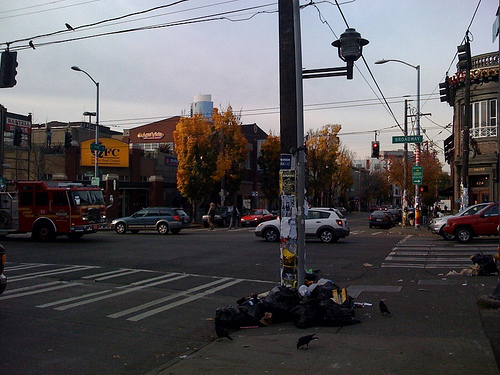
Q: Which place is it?
A: It is a road.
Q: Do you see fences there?
A: No, there are no fences.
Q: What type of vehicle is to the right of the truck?
A: The vehicle is a car.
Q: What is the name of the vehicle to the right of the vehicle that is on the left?
A: The vehicle is a car.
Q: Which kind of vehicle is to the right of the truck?
A: The vehicle is a car.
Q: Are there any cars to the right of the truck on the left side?
A: Yes, there is a car to the right of the truck.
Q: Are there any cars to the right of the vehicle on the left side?
A: Yes, there is a car to the right of the truck.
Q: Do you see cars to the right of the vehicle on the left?
A: Yes, there is a car to the right of the truck.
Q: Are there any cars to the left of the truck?
A: No, the car is to the right of the truck.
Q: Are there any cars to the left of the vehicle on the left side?
A: No, the car is to the right of the truck.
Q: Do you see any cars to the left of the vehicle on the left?
A: No, the car is to the right of the truck.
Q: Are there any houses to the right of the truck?
A: No, there is a car to the right of the truck.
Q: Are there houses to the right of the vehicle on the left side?
A: No, there is a car to the right of the truck.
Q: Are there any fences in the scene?
A: No, there are no fences.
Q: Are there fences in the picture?
A: No, there are no fences.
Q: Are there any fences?
A: No, there are no fences.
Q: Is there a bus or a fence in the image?
A: No, there are no fences or buses.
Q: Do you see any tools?
A: No, there are no tools.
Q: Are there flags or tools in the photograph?
A: No, there are no tools or flags.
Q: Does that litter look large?
A: Yes, the litter is large.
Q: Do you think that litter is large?
A: Yes, the litter is large.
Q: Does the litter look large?
A: Yes, the litter is large.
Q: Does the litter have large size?
A: Yes, the litter is large.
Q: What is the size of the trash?
A: The trash is large.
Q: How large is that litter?
A: The litter is large.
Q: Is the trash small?
A: No, the trash is large.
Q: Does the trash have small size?
A: No, the trash is large.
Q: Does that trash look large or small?
A: The trash is large.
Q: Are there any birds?
A: Yes, there is a bird.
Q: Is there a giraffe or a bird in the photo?
A: Yes, there is a bird.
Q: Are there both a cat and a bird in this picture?
A: No, there is a bird but no cats.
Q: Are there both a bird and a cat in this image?
A: No, there is a bird but no cats.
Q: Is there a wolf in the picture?
A: No, there are no wolves.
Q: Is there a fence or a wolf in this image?
A: No, there are no wolves or fences.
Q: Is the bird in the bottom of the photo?
A: Yes, the bird is in the bottom of the image.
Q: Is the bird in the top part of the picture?
A: No, the bird is in the bottom of the image.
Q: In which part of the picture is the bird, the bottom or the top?
A: The bird is in the bottom of the image.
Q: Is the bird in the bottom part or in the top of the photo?
A: The bird is in the bottom of the image.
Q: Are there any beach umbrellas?
A: No, there are no beach umbrellas.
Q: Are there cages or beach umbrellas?
A: No, there are no beach umbrellas or cages.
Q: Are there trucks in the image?
A: Yes, there is a truck.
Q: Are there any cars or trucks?
A: Yes, there is a truck.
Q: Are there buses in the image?
A: No, there are no buses.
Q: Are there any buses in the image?
A: No, there are no buses.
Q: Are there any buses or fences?
A: No, there are no buses or fences.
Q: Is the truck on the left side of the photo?
A: Yes, the truck is on the left of the image.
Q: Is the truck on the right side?
A: No, the truck is on the left of the image.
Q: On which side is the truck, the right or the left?
A: The truck is on the left of the image.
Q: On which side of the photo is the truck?
A: The truck is on the left of the image.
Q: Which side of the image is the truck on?
A: The truck is on the left of the image.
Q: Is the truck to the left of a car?
A: Yes, the truck is to the left of a car.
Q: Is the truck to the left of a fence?
A: No, the truck is to the left of a car.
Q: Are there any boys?
A: No, there are no boys.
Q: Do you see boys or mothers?
A: No, there are no boys or mothers.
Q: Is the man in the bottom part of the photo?
A: Yes, the man is in the bottom of the image.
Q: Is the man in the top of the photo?
A: No, the man is in the bottom of the image.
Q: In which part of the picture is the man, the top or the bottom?
A: The man is in the bottom of the image.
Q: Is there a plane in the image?
A: No, there are no airplanes.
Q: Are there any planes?
A: No, there are no planes.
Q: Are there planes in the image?
A: No, there are no planes.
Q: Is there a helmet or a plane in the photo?
A: No, there are no airplanes or helmets.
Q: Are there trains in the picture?
A: No, there are no trains.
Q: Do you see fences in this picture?
A: No, there are no fences.